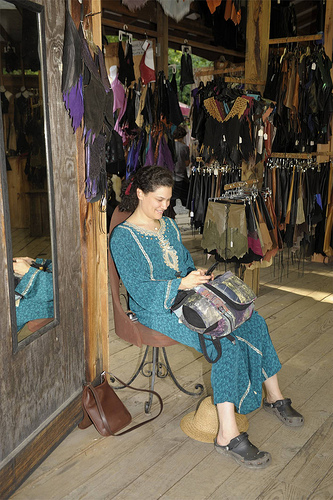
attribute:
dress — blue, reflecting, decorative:
[106, 215, 282, 416]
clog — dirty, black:
[211, 430, 272, 470]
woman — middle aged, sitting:
[106, 163, 306, 469]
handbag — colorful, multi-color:
[172, 269, 257, 364]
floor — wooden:
[0, 215, 332, 500]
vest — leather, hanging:
[76, 35, 115, 139]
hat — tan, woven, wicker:
[178, 394, 253, 445]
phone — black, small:
[205, 259, 221, 280]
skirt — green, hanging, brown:
[195, 197, 252, 262]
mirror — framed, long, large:
[1, 1, 61, 359]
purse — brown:
[77, 370, 168, 438]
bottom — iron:
[107, 346, 206, 414]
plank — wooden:
[255, 414, 332, 499]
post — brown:
[153, 0, 167, 166]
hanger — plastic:
[208, 184, 250, 204]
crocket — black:
[261, 396, 306, 427]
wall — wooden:
[1, 0, 111, 499]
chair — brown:
[95, 199, 206, 414]